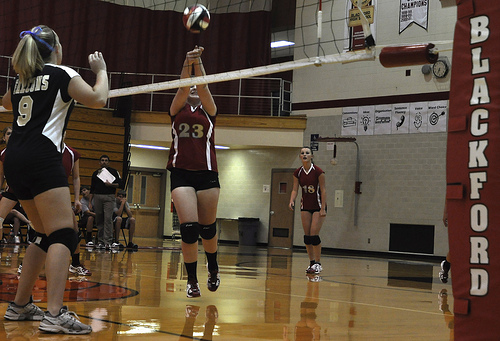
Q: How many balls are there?
A: 1.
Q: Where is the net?
A: Between the teams.